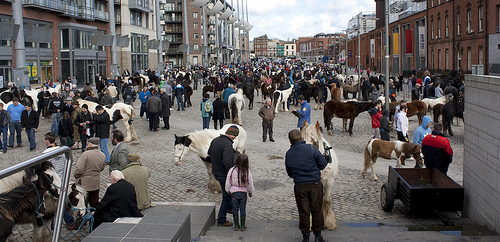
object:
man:
[94, 170, 142, 231]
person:
[291, 95, 313, 134]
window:
[194, 23, 199, 29]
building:
[157, 0, 183, 71]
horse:
[173, 124, 248, 194]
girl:
[224, 154, 253, 231]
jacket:
[118, 163, 150, 211]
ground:
[149, 132, 171, 157]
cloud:
[281, 6, 318, 31]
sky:
[259, 8, 310, 47]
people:
[258, 97, 275, 143]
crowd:
[0, 58, 466, 242]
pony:
[359, 139, 423, 181]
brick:
[354, 194, 405, 221]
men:
[115, 154, 152, 211]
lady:
[72, 104, 94, 155]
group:
[43, 72, 124, 143]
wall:
[456, 98, 493, 176]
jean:
[231, 192, 249, 227]